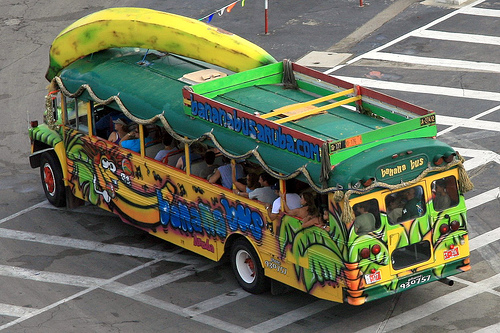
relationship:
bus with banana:
[30, 5, 472, 309] [46, 8, 280, 83]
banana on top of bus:
[46, 8, 280, 83] [30, 5, 472, 309]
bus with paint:
[30, 5, 472, 309] [39, 125, 466, 305]